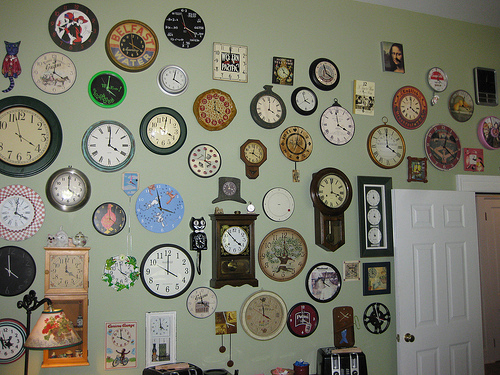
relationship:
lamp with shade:
[16, 290, 82, 374] [21, 307, 88, 356]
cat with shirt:
[1, 36, 27, 94] [1, 54, 21, 76]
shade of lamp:
[21, 307, 88, 356] [16, 290, 82, 374]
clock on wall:
[131, 184, 187, 241] [2, 2, 500, 375]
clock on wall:
[156, 63, 189, 98] [2, 2, 500, 375]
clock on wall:
[208, 41, 250, 84] [2, 2, 500, 375]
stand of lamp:
[17, 289, 52, 374] [16, 290, 82, 374]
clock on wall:
[188, 215, 213, 276] [2, 2, 500, 375]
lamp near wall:
[16, 290, 82, 374] [2, 2, 500, 375]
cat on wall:
[1, 36, 27, 94] [2, 2, 500, 375]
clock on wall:
[86, 67, 128, 111] [2, 2, 500, 375]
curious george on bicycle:
[115, 347, 132, 357] [110, 354, 131, 366]